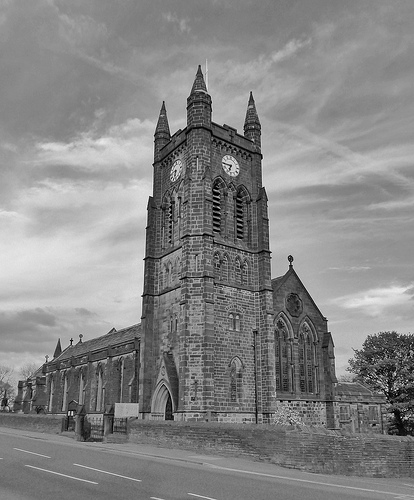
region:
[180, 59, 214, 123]
stone tower with pointed roof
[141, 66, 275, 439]
old stone clock tower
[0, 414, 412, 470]
high brick wall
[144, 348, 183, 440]
arched doorway with symbol aboe entrance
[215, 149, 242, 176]
clock face showing 6:45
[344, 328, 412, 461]
bushy tree leaning left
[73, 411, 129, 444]
tall metal gate with stone pillars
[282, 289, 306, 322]
decorative octagonal window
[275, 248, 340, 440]
old building with arched stained glass windows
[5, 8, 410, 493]
cathedral-style building in black and white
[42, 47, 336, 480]
old brick church by side of road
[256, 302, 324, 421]
high arched windows with decorative panes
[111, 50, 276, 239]
spires on top of clocktower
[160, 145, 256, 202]
white clock faces with black hands and numbers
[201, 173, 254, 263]
long window with slanted panels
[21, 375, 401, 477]
brick wall on side of church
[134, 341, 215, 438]
thick arched doorway at tower base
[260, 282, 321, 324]
window shaped like a rosette in center of wall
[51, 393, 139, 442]
metal gate and railings in brick fence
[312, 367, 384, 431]
attached shorter building with two windows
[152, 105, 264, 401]
this is a church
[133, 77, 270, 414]
the church is tall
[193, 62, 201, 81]
the top is sharp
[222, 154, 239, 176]
the church has a clock on its wall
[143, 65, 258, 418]
the church walls are grey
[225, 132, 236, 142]
a cross is placed on the walls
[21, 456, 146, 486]
the road has white strips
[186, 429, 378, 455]
the church has wall surrounding it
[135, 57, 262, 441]
the walls are old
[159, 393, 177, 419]
the door is closed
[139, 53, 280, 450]
Large clock tower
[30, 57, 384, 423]
Large building made with bricks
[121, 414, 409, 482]
Brick wall surrounding the building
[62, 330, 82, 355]
Cross on top of the building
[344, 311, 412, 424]
Tree growing on the property of the church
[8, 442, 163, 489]
Traffic lines painted in the road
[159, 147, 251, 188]
Two clock faces on the building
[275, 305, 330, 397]
Two large windows on the side of the building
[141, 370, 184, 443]
Doorway with an arch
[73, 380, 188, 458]
Main entrance to the building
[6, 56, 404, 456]
Building is a church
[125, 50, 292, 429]
Tower of church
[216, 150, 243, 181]
Clock on top of the tower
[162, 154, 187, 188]
Clock on top of the tower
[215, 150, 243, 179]
Clock has roman numerals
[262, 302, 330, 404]
Windows of a church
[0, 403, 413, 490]
Fence of church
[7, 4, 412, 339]
Sky is dark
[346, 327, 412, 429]
Tree on right side of church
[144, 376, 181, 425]
Main door entrance of church